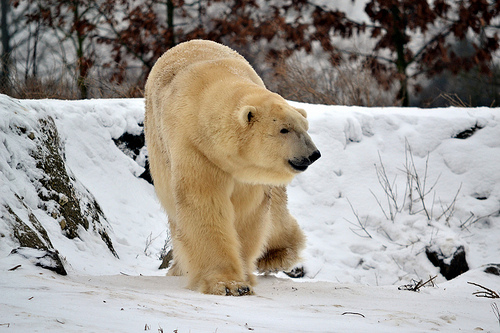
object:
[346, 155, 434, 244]
snow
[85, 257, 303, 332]
ground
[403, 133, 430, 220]
branches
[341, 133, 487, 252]
stick plant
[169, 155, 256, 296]
legs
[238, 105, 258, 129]
ear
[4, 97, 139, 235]
snow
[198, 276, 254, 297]
foot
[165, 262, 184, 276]
foot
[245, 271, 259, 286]
foot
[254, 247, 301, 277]
foot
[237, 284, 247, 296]
claws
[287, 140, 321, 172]
snout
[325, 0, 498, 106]
trees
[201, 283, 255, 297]
edge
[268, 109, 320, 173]
face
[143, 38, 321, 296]
bear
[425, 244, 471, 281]
rock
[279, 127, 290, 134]
eye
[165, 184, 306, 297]
all fours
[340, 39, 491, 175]
colder regions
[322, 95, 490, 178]
hillside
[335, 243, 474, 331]
ground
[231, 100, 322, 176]
head